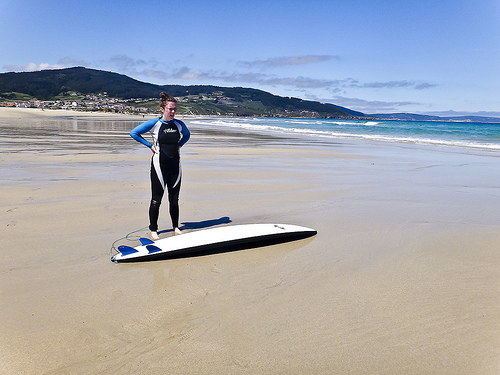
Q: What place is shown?
A: It is a beach.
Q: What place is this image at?
A: It is at the beach.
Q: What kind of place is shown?
A: It is a beach.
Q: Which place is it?
A: It is a beach.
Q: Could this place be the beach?
A: Yes, it is the beach.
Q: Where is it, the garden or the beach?
A: It is the beach.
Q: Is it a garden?
A: No, it is a beach.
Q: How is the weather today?
A: It is clear.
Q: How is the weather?
A: It is clear.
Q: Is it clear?
A: Yes, it is clear.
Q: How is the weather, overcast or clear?
A: It is clear.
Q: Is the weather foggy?
A: No, it is clear.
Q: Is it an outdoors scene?
A: Yes, it is outdoors.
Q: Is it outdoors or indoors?
A: It is outdoors.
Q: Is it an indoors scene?
A: No, it is outdoors.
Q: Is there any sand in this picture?
A: Yes, there is sand.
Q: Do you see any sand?
A: Yes, there is sand.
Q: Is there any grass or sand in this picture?
A: Yes, there is sand.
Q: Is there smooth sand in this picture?
A: Yes, there is smooth sand.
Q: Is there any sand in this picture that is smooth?
A: Yes, there is sand that is smooth.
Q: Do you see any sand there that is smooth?
A: Yes, there is sand that is smooth.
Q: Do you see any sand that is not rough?
A: Yes, there is smooth sand.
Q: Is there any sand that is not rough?
A: Yes, there is smooth sand.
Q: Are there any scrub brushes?
A: No, there are no scrub brushes.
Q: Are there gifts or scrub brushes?
A: No, there are no scrub brushes or gifts.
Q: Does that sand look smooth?
A: Yes, the sand is smooth.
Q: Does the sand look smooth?
A: Yes, the sand is smooth.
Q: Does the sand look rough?
A: No, the sand is smooth.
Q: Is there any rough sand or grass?
A: No, there is sand but it is smooth.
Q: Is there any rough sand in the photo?
A: No, there is sand but it is smooth.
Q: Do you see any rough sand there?
A: No, there is sand but it is smooth.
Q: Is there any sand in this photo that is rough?
A: No, there is sand but it is smooth.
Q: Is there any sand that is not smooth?
A: No, there is sand but it is smooth.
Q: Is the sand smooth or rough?
A: The sand is smooth.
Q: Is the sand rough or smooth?
A: The sand is smooth.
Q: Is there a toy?
A: No, there are no toys.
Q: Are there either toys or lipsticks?
A: No, there are no toys or lipsticks.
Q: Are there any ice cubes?
A: No, there are no ice cubes.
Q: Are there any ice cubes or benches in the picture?
A: No, there are no ice cubes or benches.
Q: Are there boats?
A: No, there are no boats.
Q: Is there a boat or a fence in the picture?
A: No, there are no boats or fences.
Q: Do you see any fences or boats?
A: No, there are no boats or fences.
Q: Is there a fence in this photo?
A: No, there are no fences.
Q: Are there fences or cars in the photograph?
A: No, there are no fences or cars.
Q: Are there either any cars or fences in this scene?
A: No, there are no fences or cars.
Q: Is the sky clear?
A: Yes, the sky is clear.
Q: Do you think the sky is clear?
A: Yes, the sky is clear.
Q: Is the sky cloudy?
A: No, the sky is clear.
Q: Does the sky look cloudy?
A: No, the sky is clear.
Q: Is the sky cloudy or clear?
A: The sky is clear.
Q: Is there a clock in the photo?
A: No, there are no clocks.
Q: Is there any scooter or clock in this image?
A: No, there are no clocks or scooters.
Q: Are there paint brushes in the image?
A: No, there are no paint brushes.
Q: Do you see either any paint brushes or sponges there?
A: No, there are no paint brushes or sponges.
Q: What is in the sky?
A: The clouds are in the sky.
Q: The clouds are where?
A: The clouds are in the sky.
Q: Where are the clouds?
A: The clouds are in the sky.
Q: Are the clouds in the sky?
A: Yes, the clouds are in the sky.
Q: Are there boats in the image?
A: No, there are no boats.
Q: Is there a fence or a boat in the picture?
A: No, there are no boats or fences.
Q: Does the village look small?
A: Yes, the village is small.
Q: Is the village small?
A: Yes, the village is small.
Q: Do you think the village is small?
A: Yes, the village is small.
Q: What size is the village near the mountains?
A: The village is small.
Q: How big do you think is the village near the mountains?
A: The village is small.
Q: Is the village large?
A: No, the village is small.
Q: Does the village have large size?
A: No, the village is small.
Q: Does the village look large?
A: No, the village is small.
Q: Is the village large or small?
A: The village is small.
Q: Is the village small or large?
A: The village is small.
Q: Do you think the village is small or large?
A: The village is small.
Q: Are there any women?
A: Yes, there is a woman.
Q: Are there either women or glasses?
A: Yes, there is a woman.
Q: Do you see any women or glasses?
A: Yes, there is a woman.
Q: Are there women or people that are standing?
A: Yes, the woman is standing.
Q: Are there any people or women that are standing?
A: Yes, the woman is standing.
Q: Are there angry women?
A: Yes, there is an angry woman.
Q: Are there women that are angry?
A: Yes, there is a woman that is angry.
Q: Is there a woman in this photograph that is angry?
A: Yes, there is a woman that is angry.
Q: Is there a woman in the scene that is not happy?
A: Yes, there is a angry woman.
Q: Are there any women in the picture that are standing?
A: Yes, there is a woman that is standing.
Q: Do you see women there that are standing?
A: Yes, there is a woman that is standing.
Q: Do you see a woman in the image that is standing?
A: Yes, there is a woman that is standing.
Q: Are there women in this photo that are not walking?
A: Yes, there is a woman that is standing.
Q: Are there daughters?
A: No, there are no daughters.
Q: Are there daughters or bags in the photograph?
A: No, there are no daughters or bags.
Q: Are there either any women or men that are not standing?
A: No, there is a woman but she is standing.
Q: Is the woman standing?
A: Yes, the woman is standing.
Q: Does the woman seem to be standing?
A: Yes, the woman is standing.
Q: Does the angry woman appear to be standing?
A: Yes, the woman is standing.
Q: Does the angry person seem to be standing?
A: Yes, the woman is standing.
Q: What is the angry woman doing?
A: The woman is standing.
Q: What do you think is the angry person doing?
A: The woman is standing.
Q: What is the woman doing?
A: The woman is standing.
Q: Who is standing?
A: The woman is standing.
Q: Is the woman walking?
A: No, the woman is standing.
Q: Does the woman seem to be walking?
A: No, the woman is standing.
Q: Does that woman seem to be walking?
A: No, the woman is standing.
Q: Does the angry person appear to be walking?
A: No, the woman is standing.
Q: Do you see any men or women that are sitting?
A: No, there is a woman but she is standing.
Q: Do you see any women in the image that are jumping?
A: No, there is a woman but she is standing.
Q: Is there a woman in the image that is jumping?
A: No, there is a woman but she is standing.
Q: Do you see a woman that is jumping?
A: No, there is a woman but she is standing.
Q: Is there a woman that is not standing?
A: No, there is a woman but she is standing.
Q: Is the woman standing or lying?
A: The woman is standing.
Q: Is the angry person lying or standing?
A: The woman is standing.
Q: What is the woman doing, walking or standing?
A: The woman is standing.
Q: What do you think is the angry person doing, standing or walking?
A: The woman is standing.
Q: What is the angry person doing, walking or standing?
A: The woman is standing.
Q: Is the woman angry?
A: Yes, the woman is angry.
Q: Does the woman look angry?
A: Yes, the woman is angry.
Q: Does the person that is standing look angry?
A: Yes, the woman is angry.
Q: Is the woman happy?
A: No, the woman is angry.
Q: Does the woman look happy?
A: No, the woman is angry.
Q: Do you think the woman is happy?
A: No, the woman is angry.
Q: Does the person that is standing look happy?
A: No, the woman is angry.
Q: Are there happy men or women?
A: No, there is a woman but she is angry.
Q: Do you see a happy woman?
A: No, there is a woman but she is angry.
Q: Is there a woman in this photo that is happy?
A: No, there is a woman but she is angry.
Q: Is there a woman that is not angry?
A: No, there is a woman but she is angry.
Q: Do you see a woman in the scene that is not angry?
A: No, there is a woman but she is angry.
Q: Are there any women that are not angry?
A: No, there is a woman but she is angry.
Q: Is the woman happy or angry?
A: The woman is angry.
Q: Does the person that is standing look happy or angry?
A: The woman is angry.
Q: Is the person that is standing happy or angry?
A: The woman is angry.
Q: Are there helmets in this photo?
A: No, there are no helmets.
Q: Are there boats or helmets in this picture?
A: No, there are no helmets or boats.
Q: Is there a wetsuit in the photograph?
A: Yes, there is a wetsuit.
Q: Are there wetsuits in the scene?
A: Yes, there is a wetsuit.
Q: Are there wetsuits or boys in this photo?
A: Yes, there is a wetsuit.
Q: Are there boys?
A: No, there are no boys.